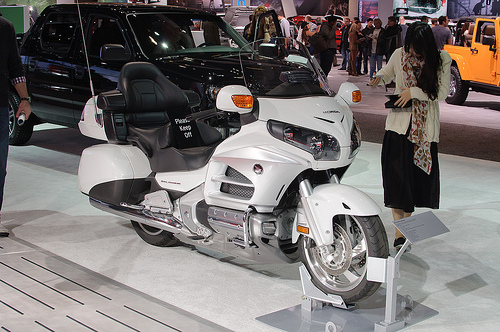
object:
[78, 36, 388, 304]
motorcycle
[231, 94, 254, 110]
light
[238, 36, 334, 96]
windshield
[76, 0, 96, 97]
antenna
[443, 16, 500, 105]
truck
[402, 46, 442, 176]
scarf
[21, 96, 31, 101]
watch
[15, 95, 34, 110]
wrist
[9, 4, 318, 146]
truck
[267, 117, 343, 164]
headlight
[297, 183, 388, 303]
wheel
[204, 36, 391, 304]
front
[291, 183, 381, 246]
fender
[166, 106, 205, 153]
sign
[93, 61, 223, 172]
upholstery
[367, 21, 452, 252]
woman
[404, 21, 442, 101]
hair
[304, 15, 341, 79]
people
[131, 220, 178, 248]
tire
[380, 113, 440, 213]
skirt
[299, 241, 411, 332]
support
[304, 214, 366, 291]
spokes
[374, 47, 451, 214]
dress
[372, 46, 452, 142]
shirt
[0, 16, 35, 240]
man